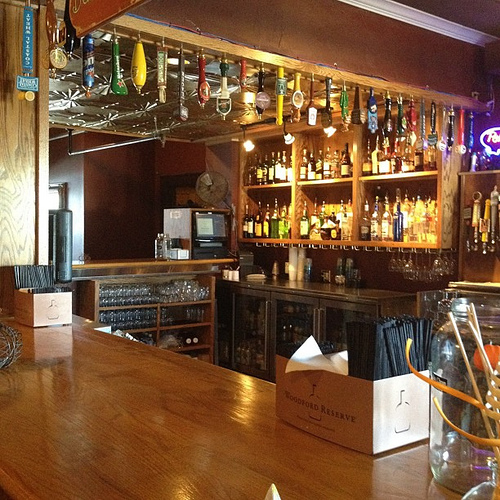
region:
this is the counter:
[75, 378, 197, 493]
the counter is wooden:
[43, 357, 155, 478]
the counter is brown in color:
[47, 364, 159, 488]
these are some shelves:
[236, 150, 461, 265]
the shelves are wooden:
[237, 158, 242, 218]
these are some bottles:
[247, 148, 436, 245]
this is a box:
[292, 377, 365, 423]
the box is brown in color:
[331, 386, 348, 398]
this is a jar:
[440, 306, 495, 453]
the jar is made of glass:
[465, 297, 487, 315]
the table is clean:
[48, 362, 231, 483]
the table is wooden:
[68, 384, 247, 493]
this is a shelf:
[234, 292, 285, 332]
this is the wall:
[92, 155, 144, 214]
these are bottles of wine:
[249, 139, 427, 226]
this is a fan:
[192, 168, 227, 201]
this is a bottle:
[51, 205, 76, 281]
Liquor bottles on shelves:
[239, 111, 449, 247]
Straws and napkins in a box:
[275, 313, 438, 459]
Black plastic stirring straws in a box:
[346, 313, 431, 398]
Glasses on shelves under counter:
[98, 268, 207, 345]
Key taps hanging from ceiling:
[50, 24, 477, 158]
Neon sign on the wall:
[476, 110, 498, 170]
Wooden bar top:
[0, 314, 465, 498]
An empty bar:
[0, 5, 497, 498]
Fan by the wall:
[196, 170, 237, 213]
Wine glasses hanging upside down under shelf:
[387, 240, 455, 287]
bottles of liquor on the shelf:
[249, 153, 302, 173]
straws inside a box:
[343, 295, 432, 385]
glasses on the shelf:
[98, 277, 215, 308]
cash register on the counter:
[190, 205, 235, 253]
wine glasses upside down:
[393, 247, 454, 284]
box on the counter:
[260, 334, 435, 464]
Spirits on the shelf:
[365, 188, 440, 245]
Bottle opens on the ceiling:
[103, 29, 468, 161]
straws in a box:
[346, 309, 423, 377]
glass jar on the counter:
[439, 296, 496, 492]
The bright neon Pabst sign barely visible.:
[464, 108, 499, 170]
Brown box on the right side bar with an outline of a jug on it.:
[273, 340, 429, 457]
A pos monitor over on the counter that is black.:
[193, 210, 228, 258]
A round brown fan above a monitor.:
[195, 169, 230, 206]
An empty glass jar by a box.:
[429, 295, 498, 492]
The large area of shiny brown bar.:
[1, 312, 461, 498]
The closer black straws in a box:
[345, 314, 428, 381]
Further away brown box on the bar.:
[10, 286, 72, 328]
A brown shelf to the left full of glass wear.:
[83, 272, 218, 365]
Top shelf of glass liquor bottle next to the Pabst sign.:
[363, 134, 438, 174]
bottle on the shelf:
[277, 206, 287, 234]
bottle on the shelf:
[299, 200, 309, 238]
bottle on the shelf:
[311, 201, 320, 237]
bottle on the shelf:
[330, 203, 340, 235]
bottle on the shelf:
[370, 197, 380, 235]